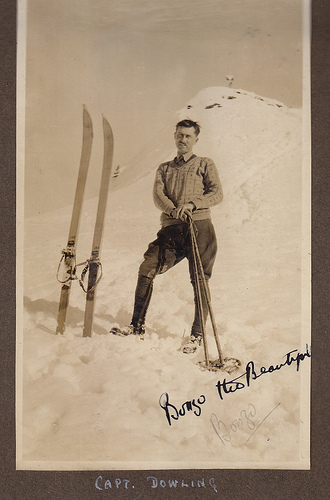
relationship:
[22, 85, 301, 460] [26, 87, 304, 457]
snow on ground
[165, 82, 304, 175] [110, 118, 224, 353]
mountain top above man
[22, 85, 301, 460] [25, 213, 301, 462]
snow on ground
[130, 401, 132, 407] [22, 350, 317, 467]
snow on ground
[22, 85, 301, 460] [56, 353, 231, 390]
snow on ground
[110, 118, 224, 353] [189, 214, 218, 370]
man holds pole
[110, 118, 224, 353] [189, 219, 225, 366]
man holds pole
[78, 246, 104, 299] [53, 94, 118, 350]
belted loops on skis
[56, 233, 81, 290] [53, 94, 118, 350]
belted loops on skis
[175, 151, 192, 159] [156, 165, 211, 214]
shirt under sweater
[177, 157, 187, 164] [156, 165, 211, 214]
tie under sweater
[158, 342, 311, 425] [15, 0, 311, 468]
signature on photo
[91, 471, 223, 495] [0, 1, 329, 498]
writing under photo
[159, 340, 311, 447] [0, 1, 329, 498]
writing under photo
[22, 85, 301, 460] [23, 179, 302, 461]
snow on ground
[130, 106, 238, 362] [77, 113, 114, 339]
man has ski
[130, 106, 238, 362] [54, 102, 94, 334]
man has ski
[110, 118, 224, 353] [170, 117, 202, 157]
man has head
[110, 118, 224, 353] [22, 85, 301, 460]
man standing in snow